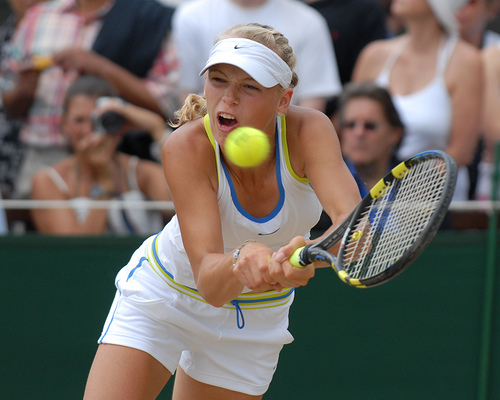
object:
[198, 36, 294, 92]
visor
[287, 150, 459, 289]
racket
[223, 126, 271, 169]
ball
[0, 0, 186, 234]
man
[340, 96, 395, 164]
face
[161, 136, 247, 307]
arm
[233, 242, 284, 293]
hand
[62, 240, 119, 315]
wall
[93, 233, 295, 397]
short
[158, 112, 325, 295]
shirt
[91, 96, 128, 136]
camera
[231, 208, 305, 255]
tank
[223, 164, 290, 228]
neckline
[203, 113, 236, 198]
line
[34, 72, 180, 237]
person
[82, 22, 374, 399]
player